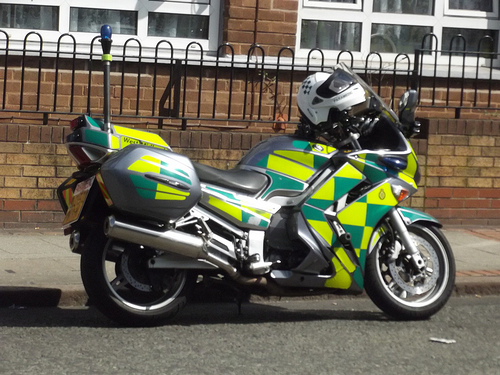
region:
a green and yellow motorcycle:
[56, 62, 454, 329]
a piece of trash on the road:
[429, 334, 457, 346]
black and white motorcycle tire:
[363, 219, 457, 322]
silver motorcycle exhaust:
[98, 213, 213, 263]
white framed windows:
[293, 0, 498, 79]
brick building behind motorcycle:
[1, 52, 498, 228]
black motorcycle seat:
[192, 161, 269, 191]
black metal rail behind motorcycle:
[0, 29, 498, 126]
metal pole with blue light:
[95, 22, 117, 126]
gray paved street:
[0, 294, 497, 373]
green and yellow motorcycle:
[40, 50, 460, 333]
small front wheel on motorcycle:
[361, 197, 461, 329]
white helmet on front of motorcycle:
[274, 59, 379, 141]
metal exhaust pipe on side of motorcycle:
[99, 206, 271, 289]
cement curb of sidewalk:
[1, 275, 498, 314]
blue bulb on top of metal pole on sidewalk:
[87, 22, 117, 53]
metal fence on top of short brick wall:
[0, 25, 497, 117]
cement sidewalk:
[0, 215, 497, 310]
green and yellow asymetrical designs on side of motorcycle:
[256, 149, 379, 271]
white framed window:
[287, 0, 498, 92]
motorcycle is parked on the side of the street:
[57, 62, 459, 323]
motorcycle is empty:
[60, 68, 457, 320]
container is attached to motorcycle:
[97, 141, 197, 222]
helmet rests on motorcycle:
[294, 71, 366, 128]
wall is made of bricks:
[1, 109, 497, 227]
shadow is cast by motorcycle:
[0, 284, 418, 329]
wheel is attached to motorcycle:
[362, 209, 457, 321]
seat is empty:
[172, 152, 268, 201]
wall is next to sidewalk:
[0, 25, 498, 222]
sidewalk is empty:
[1, 216, 497, 312]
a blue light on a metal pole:
[97, 22, 115, 124]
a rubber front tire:
[368, 218, 460, 319]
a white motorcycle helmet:
[290, 67, 367, 125]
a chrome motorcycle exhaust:
[101, 215, 215, 255]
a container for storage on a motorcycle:
[99, 150, 200, 218]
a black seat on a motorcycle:
[189, 155, 269, 193]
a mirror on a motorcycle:
[398, 90, 415, 110]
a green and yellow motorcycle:
[59, 65, 454, 321]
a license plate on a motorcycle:
[61, 175, 93, 225]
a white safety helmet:
[296, 69, 369, 124]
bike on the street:
[46, 85, 446, 317]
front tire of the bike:
[317, 198, 482, 343]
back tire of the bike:
[46, 203, 204, 335]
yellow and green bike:
[89, 125, 448, 320]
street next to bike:
[256, 314, 361, 374]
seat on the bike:
[148, 118, 305, 207]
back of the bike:
[23, 117, 195, 310]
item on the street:
[411, 318, 473, 363]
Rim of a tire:
[381, 229, 441, 297]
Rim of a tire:
[379, 230, 446, 302]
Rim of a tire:
[373, 227, 443, 304]